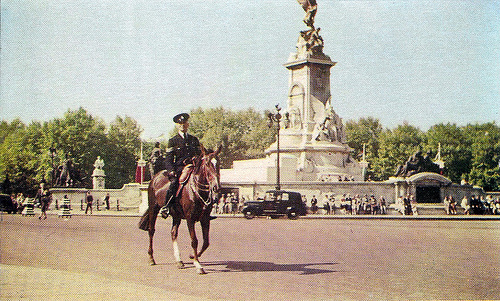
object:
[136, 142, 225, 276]
horse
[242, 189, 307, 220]
car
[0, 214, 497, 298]
street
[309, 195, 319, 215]
people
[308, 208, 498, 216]
steps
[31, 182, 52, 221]
person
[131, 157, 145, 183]
flag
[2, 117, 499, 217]
park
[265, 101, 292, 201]
lamp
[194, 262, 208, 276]
hoof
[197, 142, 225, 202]
head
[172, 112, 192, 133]
head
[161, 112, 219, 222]
man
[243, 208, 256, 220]
tire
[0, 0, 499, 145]
sky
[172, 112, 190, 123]
hat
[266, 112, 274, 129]
lights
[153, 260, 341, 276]
shadow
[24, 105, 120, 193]
trees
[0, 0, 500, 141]
background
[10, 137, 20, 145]
leaves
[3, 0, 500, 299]
day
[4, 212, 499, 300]
place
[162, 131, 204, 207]
uniform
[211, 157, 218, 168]
spot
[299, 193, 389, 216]
group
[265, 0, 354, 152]
monument